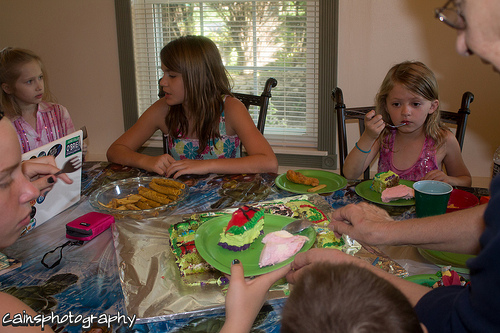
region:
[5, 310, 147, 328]
picture information in bottom left corner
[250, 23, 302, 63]
part of window blinds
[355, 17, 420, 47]
part of the wall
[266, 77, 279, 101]
top part of the chair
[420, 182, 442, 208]
a green plastic cup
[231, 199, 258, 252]
portion of the cake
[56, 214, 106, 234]
the pink carrying case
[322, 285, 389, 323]
the top of person's head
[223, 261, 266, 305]
hand holding green plate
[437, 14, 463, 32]
part of man's glasses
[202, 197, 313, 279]
cake and ice cream on green plate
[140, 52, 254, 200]
girl with long brown hair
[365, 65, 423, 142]
girl with fork to her mouth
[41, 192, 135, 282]
pink camera bag on table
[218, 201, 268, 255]
cake with red and green frosting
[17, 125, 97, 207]
plastic fork in womans hand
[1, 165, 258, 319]
silver table cloth on table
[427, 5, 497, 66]
man wearing eye glasses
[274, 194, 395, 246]
man with spoon in his hand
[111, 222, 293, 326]
cake on silver serving tray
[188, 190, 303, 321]
a green plate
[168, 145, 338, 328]
a green plate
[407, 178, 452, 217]
a plastic green cup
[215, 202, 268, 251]
a slice of cake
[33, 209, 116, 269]
a pink case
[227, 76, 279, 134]
part of a chair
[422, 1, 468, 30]
part of a man's eyeglasses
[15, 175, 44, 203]
the nose of a girl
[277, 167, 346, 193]
a circle green plate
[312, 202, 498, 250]
the arm of a man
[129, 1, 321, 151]
white mini blinds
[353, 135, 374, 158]
a small blue bracelet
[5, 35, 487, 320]
A children's party.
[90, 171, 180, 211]
A glass dish with taquitos in it.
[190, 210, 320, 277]
Food on a plastic green plate.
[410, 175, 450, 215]
A plastic cup.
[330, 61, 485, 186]
The girl is eating.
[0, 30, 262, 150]
The two girls are talking.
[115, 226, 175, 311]
Aluminum foil.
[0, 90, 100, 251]
The girl is holding a fork in her left hand.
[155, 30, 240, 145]
The girl has brown hair.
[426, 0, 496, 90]
The person is wearing glasses.